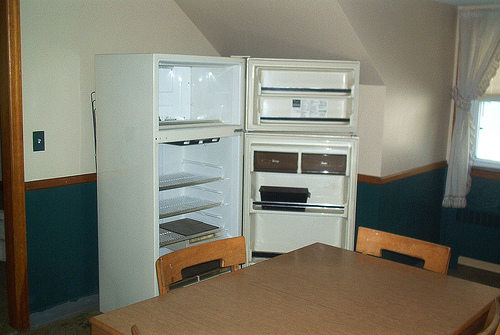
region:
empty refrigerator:
[157, 59, 243, 252]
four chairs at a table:
[126, 220, 499, 333]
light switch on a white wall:
[31, 130, 46, 150]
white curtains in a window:
[443, 2, 498, 207]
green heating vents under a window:
[451, 198, 497, 253]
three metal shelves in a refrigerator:
[157, 171, 225, 248]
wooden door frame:
[4, 0, 32, 331]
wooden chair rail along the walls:
[19, 157, 446, 203]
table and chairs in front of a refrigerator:
[81, 216, 496, 333]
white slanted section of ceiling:
[178, 0, 388, 87]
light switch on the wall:
[32, 131, 52, 151]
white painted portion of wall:
[23, 30, 90, 108]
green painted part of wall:
[30, 186, 98, 299]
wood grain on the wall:
[26, 173, 93, 190]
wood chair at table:
[356, 221, 450, 273]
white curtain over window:
[447, 21, 498, 211]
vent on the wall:
[450, 204, 497, 227]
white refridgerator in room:
[92, 53, 367, 301]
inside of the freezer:
[157, 68, 235, 116]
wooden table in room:
[101, 243, 497, 333]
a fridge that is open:
[67, 12, 476, 307]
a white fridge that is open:
[97, 31, 462, 311]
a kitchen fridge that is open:
[82, 40, 334, 317]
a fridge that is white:
[80, 18, 352, 328]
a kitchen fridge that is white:
[57, 30, 342, 325]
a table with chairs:
[149, 218, 461, 331]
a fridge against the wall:
[37, 15, 472, 305]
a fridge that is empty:
[112, 11, 432, 324]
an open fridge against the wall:
[107, 13, 465, 334]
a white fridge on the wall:
[91, 9, 335, 323]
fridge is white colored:
[91, 45, 358, 245]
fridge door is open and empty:
[84, 42, 357, 242]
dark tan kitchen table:
[88, 244, 495, 334]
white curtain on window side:
[445, 2, 496, 209]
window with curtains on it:
[460, 0, 498, 165]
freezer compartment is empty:
[142, 55, 240, 129]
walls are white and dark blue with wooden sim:
[371, 84, 434, 218]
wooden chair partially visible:
[157, 235, 245, 290]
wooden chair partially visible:
[352, 224, 450, 273]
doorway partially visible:
[1, 1, 21, 333]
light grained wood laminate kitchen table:
[85, 226, 495, 332]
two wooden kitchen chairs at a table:
[152, 224, 454, 294]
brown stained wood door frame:
[2, 0, 31, 325]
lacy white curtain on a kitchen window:
[441, 3, 496, 207]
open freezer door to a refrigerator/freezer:
[245, 56, 360, 131]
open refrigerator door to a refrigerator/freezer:
[243, 130, 360, 271]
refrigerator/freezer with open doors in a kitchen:
[92, 53, 363, 315]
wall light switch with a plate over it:
[34, 129, 46, 154]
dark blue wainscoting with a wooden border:
[23, 161, 496, 303]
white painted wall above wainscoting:
[19, 1, 454, 181]